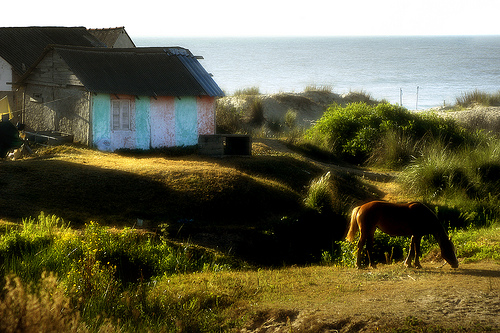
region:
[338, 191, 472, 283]
a brown horse eating grass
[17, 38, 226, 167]
a small house in the background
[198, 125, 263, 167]
a wooden stall in front of the house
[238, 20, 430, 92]
a body of water in the background.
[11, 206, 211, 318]
wild flowers growing in the field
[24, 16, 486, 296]
a seaside cottage with horse in the field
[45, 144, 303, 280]
a small hill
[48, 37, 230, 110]
the black roof on top of the house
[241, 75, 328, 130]
sand dunes at the ocean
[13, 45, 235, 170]
a small house with blue and pink plastic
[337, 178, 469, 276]
the horse is eating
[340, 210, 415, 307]
the horse is eating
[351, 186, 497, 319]
the horse is eating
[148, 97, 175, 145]
Faded red stripe on a barn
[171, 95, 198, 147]
Faded blue stripe on a barn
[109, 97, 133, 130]
Window on the side of a barn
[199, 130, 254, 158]
Wooden crate in front of a barn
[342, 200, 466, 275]
Brown horse eating grass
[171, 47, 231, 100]
Metal roof on a barn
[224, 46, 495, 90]
Water behind a barn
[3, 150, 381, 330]
Brown and green hills by a barn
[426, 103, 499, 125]
Sandy hill by the water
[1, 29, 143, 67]
Roof on a house behind a barn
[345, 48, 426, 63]
water in the distance.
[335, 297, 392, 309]
grass on the ground.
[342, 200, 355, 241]
tail of the horse.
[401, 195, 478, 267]
horse grazing in the field.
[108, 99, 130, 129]
window on the house.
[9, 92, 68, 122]
wire running to the house.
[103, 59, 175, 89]
roof of the house.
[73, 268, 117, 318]
plants near the clearing.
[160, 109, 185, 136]
paint on side of house.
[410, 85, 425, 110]
poles near the beach.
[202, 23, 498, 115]
This is the water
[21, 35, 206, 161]
this is the building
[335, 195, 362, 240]
this is a tail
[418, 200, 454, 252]
this is the mane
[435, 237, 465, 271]
this is the head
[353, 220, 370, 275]
this is the back right leg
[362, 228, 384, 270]
this is the back left leg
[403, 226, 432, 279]
the front right leg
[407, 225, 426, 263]
the front left leg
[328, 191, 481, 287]
this is a horse